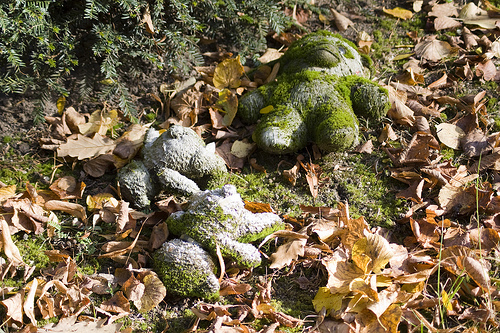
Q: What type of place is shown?
A: It is a yard.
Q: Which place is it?
A: It is a yard.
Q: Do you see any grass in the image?
A: Yes, there is grass.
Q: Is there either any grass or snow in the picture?
A: Yes, there is grass.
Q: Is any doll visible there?
A: Yes, there is a doll.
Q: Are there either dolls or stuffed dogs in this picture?
A: Yes, there is a doll.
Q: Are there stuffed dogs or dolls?
A: Yes, there is a doll.